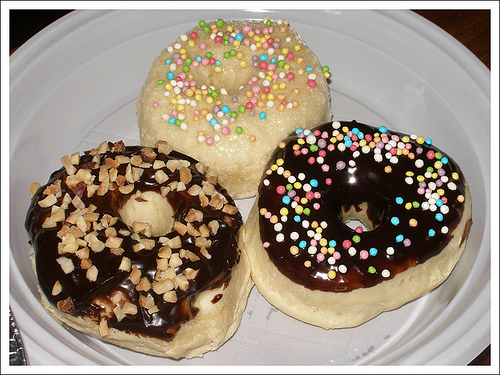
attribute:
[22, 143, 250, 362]
donut — brown, chocolaty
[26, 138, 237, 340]
peanuts — chopped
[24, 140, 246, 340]
icing — chocolate, brown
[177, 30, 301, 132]
sprinkles — colorful, pastel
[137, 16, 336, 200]
donut — glazed, tan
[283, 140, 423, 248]
sprinkles — colorful, pastel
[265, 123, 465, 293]
icing — chocolate, brown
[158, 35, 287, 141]
glaze — beige caramel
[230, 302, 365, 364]
pattern — criss cross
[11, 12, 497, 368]
bowl — white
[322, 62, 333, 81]
sprinkle — yellow, stuck together, green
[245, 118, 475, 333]
donut — brown, chocolaty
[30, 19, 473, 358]
donuts — fried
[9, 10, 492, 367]
plate — white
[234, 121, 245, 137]
sprinkle — green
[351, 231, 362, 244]
sprinkle — green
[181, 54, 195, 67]
sprinkle — green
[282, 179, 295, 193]
sprinkle — green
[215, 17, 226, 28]
sprinkle — green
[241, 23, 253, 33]
sprinkle — pink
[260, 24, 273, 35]
sprinkle — pink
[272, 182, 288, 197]
sprinkle — pink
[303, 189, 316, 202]
sprinkle — pink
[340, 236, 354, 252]
sprinkle — pink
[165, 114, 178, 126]
sprinkle — blue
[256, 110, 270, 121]
sprinkle — blue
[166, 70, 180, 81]
sprinkle — blue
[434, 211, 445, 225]
sprinkle — blue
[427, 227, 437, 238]
sprinkle — blue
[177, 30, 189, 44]
sprinkle — white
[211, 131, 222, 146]
sprinkle — white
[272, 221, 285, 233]
sprinkle — white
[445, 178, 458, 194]
sprinkle — white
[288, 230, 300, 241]
sprinkle — white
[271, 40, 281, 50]
sprinkle — purple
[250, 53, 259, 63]
sprinkle — purple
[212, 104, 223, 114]
sprinkle — purple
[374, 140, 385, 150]
sprinkle — purple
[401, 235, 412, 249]
sprinkle — purple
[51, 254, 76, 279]
nut — chopped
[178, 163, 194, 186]
nut — chopped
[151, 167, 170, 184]
nut — chopped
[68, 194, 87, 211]
nut — chopped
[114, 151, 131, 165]
nut — chopped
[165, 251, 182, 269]
walnut chunk — small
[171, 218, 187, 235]
walnut chunk — small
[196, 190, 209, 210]
walnut chunk — small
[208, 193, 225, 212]
walnut chunk — small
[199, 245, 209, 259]
walnut chunk — small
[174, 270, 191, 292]
walnut chunk — small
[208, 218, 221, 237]
walnut chunk — small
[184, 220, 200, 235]
walnut chunk — small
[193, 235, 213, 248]
walnut chunk — small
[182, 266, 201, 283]
walnut chunk — small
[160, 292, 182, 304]
walnut chunk — small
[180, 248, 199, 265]
walnut chunk — small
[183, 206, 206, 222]
walnut chunk — small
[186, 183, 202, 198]
walnut chunk — small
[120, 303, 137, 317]
walnut chunk — small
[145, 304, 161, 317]
walnut chunk — small